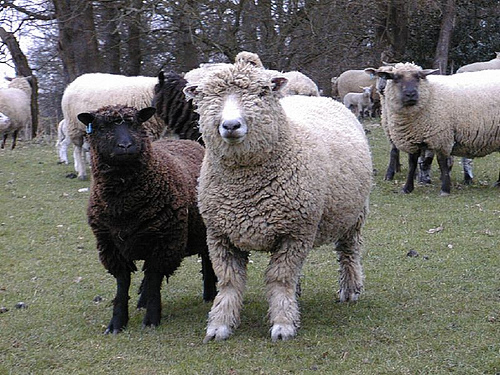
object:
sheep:
[343, 84, 374, 120]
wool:
[446, 85, 486, 121]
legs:
[402, 149, 420, 194]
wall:
[421, 130, 456, 162]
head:
[77, 103, 158, 166]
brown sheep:
[76, 105, 216, 335]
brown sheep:
[154, 71, 209, 147]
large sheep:
[182, 62, 374, 342]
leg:
[262, 234, 312, 326]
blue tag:
[85, 123, 93, 134]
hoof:
[269, 309, 299, 341]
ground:
[330, 312, 416, 355]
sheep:
[332, 66, 394, 117]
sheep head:
[180, 69, 291, 171]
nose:
[222, 119, 243, 130]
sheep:
[59, 67, 188, 178]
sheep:
[0, 75, 31, 148]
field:
[0, 179, 500, 375]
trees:
[0, 0, 493, 121]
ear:
[268, 77, 290, 93]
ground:
[395, 203, 474, 266]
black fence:
[133, 77, 332, 146]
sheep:
[375, 61, 499, 196]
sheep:
[60, 72, 176, 181]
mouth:
[220, 129, 247, 146]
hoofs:
[200, 326, 231, 344]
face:
[202, 76, 268, 145]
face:
[391, 69, 425, 105]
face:
[153, 68, 185, 103]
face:
[95, 110, 144, 161]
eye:
[258, 90, 268, 98]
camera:
[0, 0, 500, 375]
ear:
[75, 112, 95, 126]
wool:
[125, 188, 182, 228]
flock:
[1, 48, 498, 346]